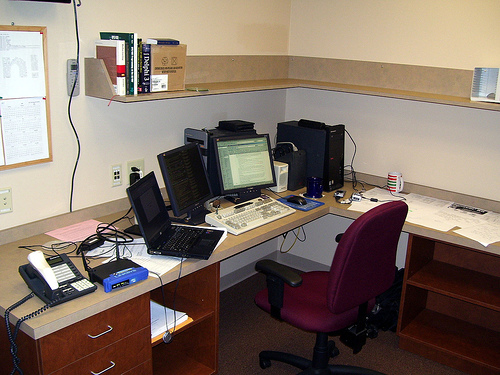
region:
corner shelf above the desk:
[86, 50, 498, 112]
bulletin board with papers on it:
[0, 27, 54, 168]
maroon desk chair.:
[262, 202, 406, 374]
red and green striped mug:
[386, 174, 403, 194]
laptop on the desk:
[124, 175, 221, 260]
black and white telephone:
[1, 249, 94, 373]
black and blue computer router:
[87, 237, 146, 295]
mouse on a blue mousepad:
[281, 193, 323, 211]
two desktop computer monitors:
[160, 136, 275, 210]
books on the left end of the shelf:
[101, 31, 153, 93]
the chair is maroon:
[236, 196, 415, 359]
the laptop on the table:
[108, 153, 237, 306]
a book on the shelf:
[90, 18, 218, 122]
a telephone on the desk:
[6, 238, 123, 310]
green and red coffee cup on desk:
[381, 168, 407, 194]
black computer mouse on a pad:
[285, 191, 313, 211]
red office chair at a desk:
[245, 190, 418, 358]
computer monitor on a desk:
[211, 130, 282, 196]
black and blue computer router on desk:
[77, 237, 153, 294]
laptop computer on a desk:
[118, 167, 230, 270]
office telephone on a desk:
[13, 235, 101, 318]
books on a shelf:
[90, 23, 191, 101]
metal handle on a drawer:
[84, 321, 117, 343]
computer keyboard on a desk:
[200, 186, 301, 237]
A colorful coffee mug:
[382, 170, 407, 191]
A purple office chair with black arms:
[250, 199, 409, 372]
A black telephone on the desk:
[17, 250, 98, 308]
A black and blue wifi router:
[76, 240, 148, 292]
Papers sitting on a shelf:
[146, 299, 193, 347]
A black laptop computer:
[124, 171, 224, 260]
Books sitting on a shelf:
[95, 31, 155, 98]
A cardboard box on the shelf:
[146, 42, 188, 91]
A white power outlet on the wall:
[125, 157, 147, 187]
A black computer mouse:
[286, 194, 307, 205]